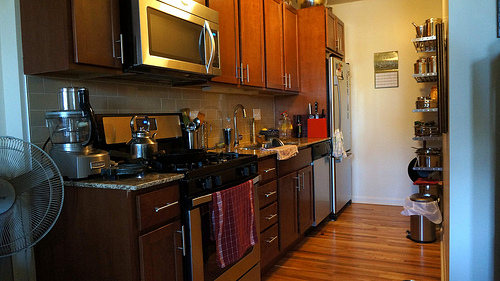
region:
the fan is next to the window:
[4, 135, 66, 268]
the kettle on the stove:
[129, 113, 158, 155]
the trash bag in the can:
[404, 199, 444, 225]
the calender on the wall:
[371, 52, 398, 89]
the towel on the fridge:
[333, 127, 345, 162]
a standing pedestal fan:
[0, 135, 64, 260]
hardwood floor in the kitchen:
[266, 200, 440, 279]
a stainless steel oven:
[94, 110, 261, 280]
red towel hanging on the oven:
[211, 177, 258, 265]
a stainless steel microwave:
[132, 0, 222, 80]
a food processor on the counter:
[45, 85, 112, 180]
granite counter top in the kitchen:
[63, 135, 332, 186]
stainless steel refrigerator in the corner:
[327, 58, 357, 218]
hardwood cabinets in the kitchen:
[20, 0, 345, 278]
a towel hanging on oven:
[199, 178, 268, 252]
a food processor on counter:
[40, 87, 115, 175]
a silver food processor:
[49, 88, 104, 191]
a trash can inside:
[400, 188, 460, 269]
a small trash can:
[394, 194, 441, 241]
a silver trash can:
[403, 192, 453, 279]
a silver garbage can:
[396, 173, 441, 261]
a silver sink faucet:
[227, 105, 247, 131]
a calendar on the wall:
[374, 44, 406, 104]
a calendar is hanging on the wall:
[367, 45, 402, 94]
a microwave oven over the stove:
[104, 0, 246, 85]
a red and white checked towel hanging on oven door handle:
[205, 176, 261, 279]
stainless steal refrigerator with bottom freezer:
[324, 55, 368, 224]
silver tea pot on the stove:
[121, 112, 165, 165]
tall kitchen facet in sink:
[229, 95, 274, 157]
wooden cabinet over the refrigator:
[310, 5, 355, 61]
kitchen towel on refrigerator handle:
[328, 123, 352, 170]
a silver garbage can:
[416, 210, 461, 272]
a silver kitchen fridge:
[329, 55, 385, 204]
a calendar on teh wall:
[361, 30, 382, 91]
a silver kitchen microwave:
[115, 5, 247, 82]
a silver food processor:
[36, 84, 123, 231]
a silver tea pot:
[117, 108, 175, 169]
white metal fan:
[0, 135, 66, 257]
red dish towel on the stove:
[211, 177, 255, 267]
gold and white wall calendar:
[373, 50, 400, 87]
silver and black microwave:
[118, 3, 221, 87]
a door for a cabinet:
[75, 0, 121, 75]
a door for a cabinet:
[212, 0, 243, 87]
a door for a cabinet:
[235, 0, 268, 85]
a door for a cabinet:
[257, 0, 283, 90]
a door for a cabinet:
[284, 5, 307, 90]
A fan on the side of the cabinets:
[0, 136, 65, 275]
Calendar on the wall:
[369, 46, 401, 89]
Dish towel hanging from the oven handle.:
[208, 176, 258, 271]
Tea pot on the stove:
[126, 107, 160, 166]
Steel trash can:
[401, 190, 443, 243]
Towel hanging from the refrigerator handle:
[331, 126, 344, 162]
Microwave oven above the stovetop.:
[101, 1, 224, 81]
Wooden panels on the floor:
[268, 198, 440, 276]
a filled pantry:
[406, 18, 443, 215]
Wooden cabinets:
[213, 0, 300, 92]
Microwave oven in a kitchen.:
[129, 0, 221, 80]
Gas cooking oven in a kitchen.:
[91, 110, 262, 280]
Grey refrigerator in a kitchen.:
[328, 55, 354, 217]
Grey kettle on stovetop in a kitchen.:
[126, 112, 158, 162]